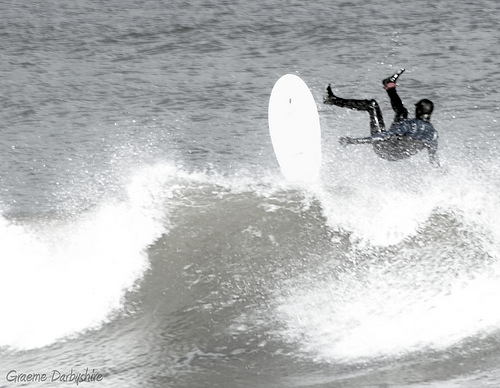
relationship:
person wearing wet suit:
[324, 68, 443, 170] [330, 86, 437, 161]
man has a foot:
[328, 67, 440, 164] [380, 68, 402, 88]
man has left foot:
[328, 67, 440, 164] [323, 83, 334, 108]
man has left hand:
[328, 67, 440, 164] [337, 135, 350, 148]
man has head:
[328, 67, 440, 164] [412, 99, 433, 120]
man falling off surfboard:
[328, 67, 440, 164] [266, 73, 320, 189]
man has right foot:
[328, 67, 440, 164] [377, 72, 398, 86]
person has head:
[324, 68, 443, 170] [412, 99, 433, 120]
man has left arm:
[328, 67, 440, 164] [358, 120, 409, 142]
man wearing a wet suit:
[328, 67, 440, 164] [330, 86, 437, 161]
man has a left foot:
[328, 67, 440, 164] [323, 83, 334, 108]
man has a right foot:
[328, 67, 440, 164] [377, 72, 398, 86]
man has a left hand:
[328, 67, 440, 164] [337, 135, 350, 148]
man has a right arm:
[328, 67, 440, 164] [424, 140, 439, 168]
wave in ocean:
[2, 156, 498, 364] [1, 2, 498, 387]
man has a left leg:
[328, 67, 440, 164] [335, 98, 384, 137]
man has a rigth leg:
[328, 67, 440, 164] [386, 86, 408, 121]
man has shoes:
[328, 67, 440, 164] [324, 68, 404, 106]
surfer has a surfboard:
[324, 68, 443, 170] [266, 73, 320, 189]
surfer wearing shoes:
[324, 68, 443, 170] [324, 68, 404, 106]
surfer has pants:
[324, 68, 443, 170] [337, 87, 407, 137]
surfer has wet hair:
[324, 68, 443, 170] [414, 98, 431, 116]